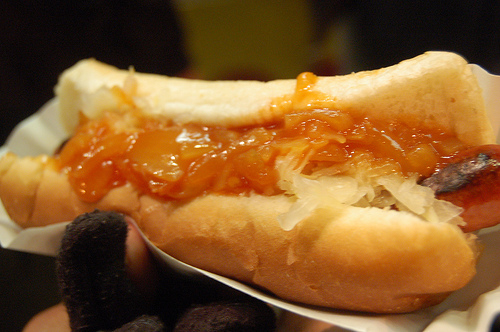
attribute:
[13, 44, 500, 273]
hot dog — brown, pink, burnt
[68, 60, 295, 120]
bread — brown, white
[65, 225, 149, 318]
gloves — black, fuzzy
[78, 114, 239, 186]
sauce — orange, buffalo, dripping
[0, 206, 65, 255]
paper — white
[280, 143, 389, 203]
sauerkraut — white, translucent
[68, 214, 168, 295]
finger — gloved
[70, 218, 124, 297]
glove — black, ripped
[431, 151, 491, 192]
spot — burnt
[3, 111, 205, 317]
wrapper — white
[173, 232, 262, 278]
crust — brown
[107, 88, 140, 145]
onions — cooked, gooey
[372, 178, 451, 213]
shreds — translucent